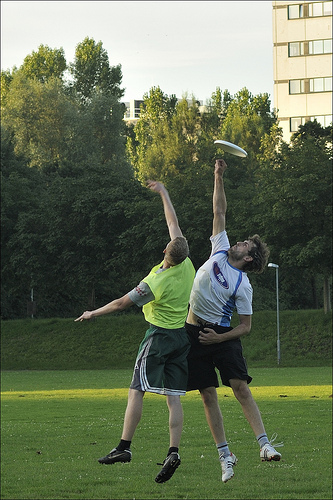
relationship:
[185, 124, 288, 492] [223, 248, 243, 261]
men has facial hair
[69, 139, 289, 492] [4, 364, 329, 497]
men in field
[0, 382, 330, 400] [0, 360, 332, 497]
light on field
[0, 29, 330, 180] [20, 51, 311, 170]
leaves on branches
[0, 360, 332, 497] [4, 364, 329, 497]
field on field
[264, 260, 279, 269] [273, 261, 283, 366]
lamp on pole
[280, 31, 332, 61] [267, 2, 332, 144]
windows on building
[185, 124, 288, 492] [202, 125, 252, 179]
men catching frisbee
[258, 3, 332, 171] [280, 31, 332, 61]
building has windows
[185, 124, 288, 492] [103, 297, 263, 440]
men wearing shorts